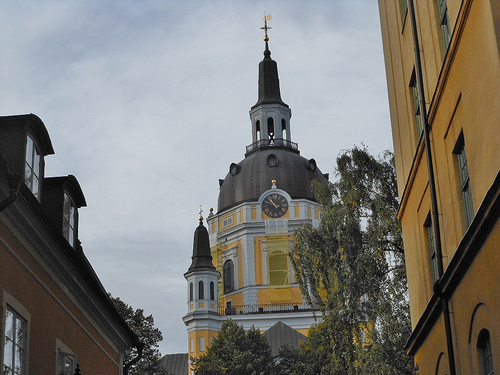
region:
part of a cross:
[240, 3, 277, 42]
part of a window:
[263, 210, 280, 243]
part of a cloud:
[126, 238, 164, 304]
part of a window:
[195, 291, 229, 348]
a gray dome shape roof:
[215, 133, 377, 218]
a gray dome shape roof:
[190, 159, 349, 234]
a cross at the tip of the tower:
[244, 6, 299, 79]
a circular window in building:
[262, 151, 279, 168]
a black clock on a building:
[258, 188, 293, 216]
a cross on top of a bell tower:
[258, 6, 278, 48]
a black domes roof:
[219, 154, 334, 199]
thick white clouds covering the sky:
[69, 5, 209, 237]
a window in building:
[437, 118, 477, 222]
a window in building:
[415, 209, 442, 283]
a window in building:
[399, 71, 431, 132]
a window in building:
[431, 2, 454, 44]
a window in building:
[2, 296, 42, 373]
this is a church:
[192, 43, 310, 329]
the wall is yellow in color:
[210, 138, 297, 303]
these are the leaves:
[308, 195, 389, 302]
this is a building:
[24, 256, 94, 367]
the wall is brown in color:
[37, 295, 70, 330]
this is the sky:
[88, 2, 225, 130]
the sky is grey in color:
[103, 13, 218, 117]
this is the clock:
[260, 193, 286, 215]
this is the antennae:
[259, 10, 274, 43]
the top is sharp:
[255, 40, 272, 62]